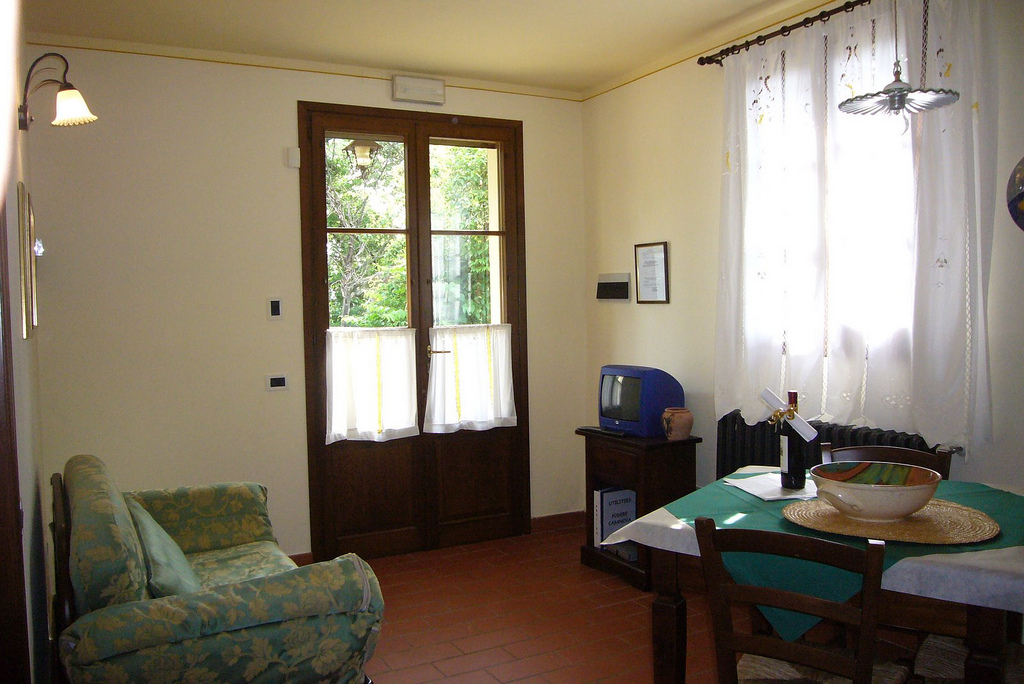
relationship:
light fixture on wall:
[18, 51, 94, 131] [1, 1, 44, 682]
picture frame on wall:
[630, 238, 672, 306] [592, 4, 1023, 491]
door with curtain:
[425, 105, 531, 552] [321, 321, 420, 448]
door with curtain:
[425, 105, 531, 552] [422, 320, 521, 434]